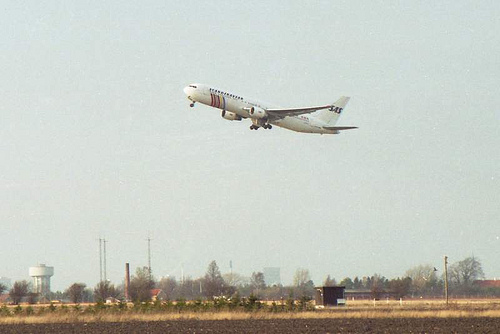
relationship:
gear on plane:
[189, 97, 200, 108] [173, 72, 365, 151]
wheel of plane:
[257, 114, 276, 133] [167, 70, 358, 146]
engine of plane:
[243, 104, 267, 124] [167, 70, 358, 146]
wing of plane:
[261, 96, 331, 127] [167, 70, 358, 146]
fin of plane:
[318, 95, 358, 125] [176, 70, 365, 140]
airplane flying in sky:
[179, 67, 371, 142] [7, 8, 493, 265]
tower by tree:
[24, 251, 75, 301] [9, 277, 34, 304]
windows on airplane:
[205, 81, 245, 104] [179, 67, 358, 158]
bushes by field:
[85, 278, 232, 309] [0, 299, 492, 323]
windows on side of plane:
[205, 81, 245, 104] [181, 77, 367, 140]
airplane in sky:
[179, 67, 371, 142] [7, 8, 493, 265]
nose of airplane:
[180, 81, 205, 106] [177, 77, 365, 140]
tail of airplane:
[319, 91, 353, 131] [175, 69, 358, 144]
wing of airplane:
[261, 96, 331, 127] [179, 76, 365, 152]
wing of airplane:
[261, 96, 331, 127] [179, 67, 371, 142]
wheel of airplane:
[257, 114, 276, 133] [179, 67, 371, 142]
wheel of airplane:
[248, 123, 260, 132] [179, 67, 371, 142]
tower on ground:
[24, 251, 75, 301] [87, 312, 160, 331]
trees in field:
[62, 279, 152, 330] [202, 314, 252, 332]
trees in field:
[62, 279, 152, 330] [49, 268, 123, 313]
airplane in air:
[179, 67, 371, 142] [84, 82, 187, 227]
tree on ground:
[181, 250, 241, 307] [178, 298, 237, 322]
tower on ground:
[24, 251, 75, 301] [25, 291, 106, 324]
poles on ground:
[89, 240, 119, 298] [86, 302, 156, 322]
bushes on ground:
[85, 278, 232, 309] [87, 312, 160, 331]